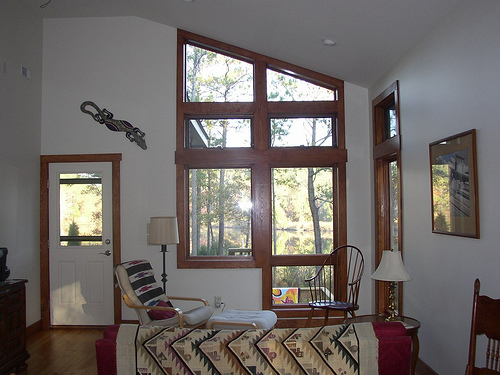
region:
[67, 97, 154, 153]
gecko figurine on wall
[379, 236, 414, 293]
white lamp shade on lamp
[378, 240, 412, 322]
lamp on end table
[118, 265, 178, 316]
blanket on white chair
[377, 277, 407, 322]
base of lamp is brass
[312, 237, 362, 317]
wooden chair in corner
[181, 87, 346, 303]
large window in living room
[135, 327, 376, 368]
blanket on back of couch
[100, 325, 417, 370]
red couch in living room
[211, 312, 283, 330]
ottoman in front of chair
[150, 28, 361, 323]
wooden framed multi paned window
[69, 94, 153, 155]
black metal decoration art on the wall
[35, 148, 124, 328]
white door with a dark wooden frame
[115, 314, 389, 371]
native American design on a tan blanket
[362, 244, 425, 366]
lamp with a white shade on an end table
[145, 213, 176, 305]
standing lamp behind a chair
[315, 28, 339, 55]
recessed light in white ceiling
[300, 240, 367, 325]
brown wooden chair with arms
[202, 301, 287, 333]
tan cushioned foot rest in front of chair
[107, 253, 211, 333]
tan chair with woven blanket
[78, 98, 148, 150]
an artistic rendition of a lizard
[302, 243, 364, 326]
a wooden chair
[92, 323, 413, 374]
a red couch with quilt thrown over it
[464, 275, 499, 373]
a brown wooden chair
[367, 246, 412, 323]
a desk lamp with white shade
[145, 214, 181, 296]
a floor lamp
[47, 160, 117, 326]
a wooden door with window painted white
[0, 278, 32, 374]
a wooden chest of drawers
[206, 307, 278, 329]
a padded foot rest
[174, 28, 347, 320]
an oddly shaped window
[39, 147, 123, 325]
the door is white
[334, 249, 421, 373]
bronze lamp on table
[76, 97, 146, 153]
lizard decoration on wall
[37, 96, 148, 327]
decoration is above door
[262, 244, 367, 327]
brown chair next to window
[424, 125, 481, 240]
picture hanging on wall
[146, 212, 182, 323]
black lamp next to window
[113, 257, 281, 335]
white chair next to wall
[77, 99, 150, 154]
decoration next to window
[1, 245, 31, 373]
dresser next to white wall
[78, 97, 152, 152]
Lizard plaque on wall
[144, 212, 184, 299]
Tall lamp with white shade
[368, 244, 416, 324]
Short lamp with white shade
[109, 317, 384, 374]
Native american designed blanket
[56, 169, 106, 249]
Window in door to outdoors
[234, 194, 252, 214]
Sun shining through window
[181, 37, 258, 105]
Trapezoid shaped window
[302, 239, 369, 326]
Windsor style wooden chair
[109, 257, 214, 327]
Platform rocker with white cushions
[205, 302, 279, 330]
Matching ottoman for platform rocker